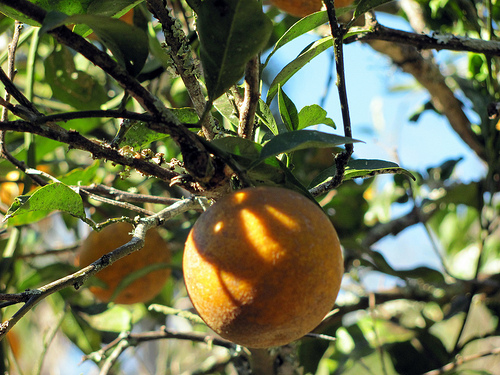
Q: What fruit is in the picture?
A: Oranges.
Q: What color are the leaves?
A: Green.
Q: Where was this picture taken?
A: An orchard.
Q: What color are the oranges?
A: Orange.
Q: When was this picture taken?
A: During the day.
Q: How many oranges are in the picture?
A: Six.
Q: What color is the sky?
A: Blue.